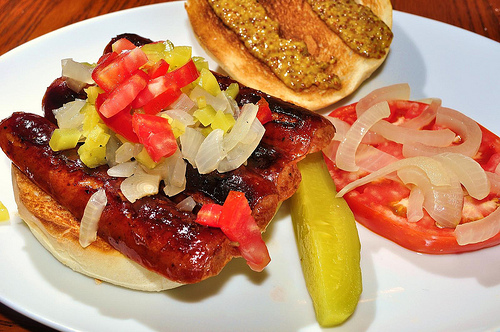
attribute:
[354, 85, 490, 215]
onions — white, diced, sliced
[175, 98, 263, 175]
onions — white, diced, sliced, chopped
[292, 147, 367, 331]
pickle — green, thinly sliced, gree, wedged, dill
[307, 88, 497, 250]
tomato — sliced, roud, red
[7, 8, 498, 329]
plate — white, roud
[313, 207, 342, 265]
seeds — tiny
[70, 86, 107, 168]
peppers — green, diced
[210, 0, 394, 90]
sauce — mustard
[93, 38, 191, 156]
tomato — chopped, red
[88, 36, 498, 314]
toppigs — vegtables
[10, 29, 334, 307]
sausage — sliced, grilled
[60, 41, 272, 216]
vegetables — chopped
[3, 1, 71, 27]
table — brow, woode, wood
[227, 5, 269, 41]
mustard — stoe groud